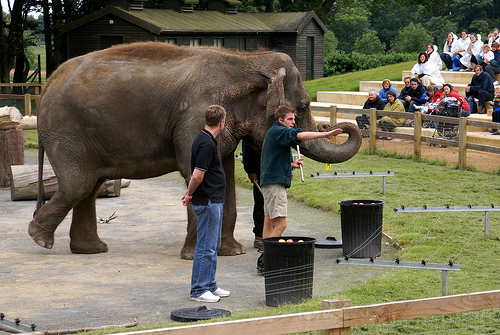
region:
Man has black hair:
[203, 105, 221, 127]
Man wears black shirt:
[194, 138, 217, 165]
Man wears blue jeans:
[191, 208, 218, 286]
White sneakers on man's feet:
[187, 274, 235, 304]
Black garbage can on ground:
[258, 231, 322, 306]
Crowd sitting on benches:
[355, 25, 498, 142]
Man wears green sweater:
[263, 127, 289, 177]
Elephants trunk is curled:
[312, 118, 363, 170]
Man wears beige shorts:
[254, 183, 297, 221]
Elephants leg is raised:
[23, 189, 64, 265]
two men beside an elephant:
[26, 40, 376, 315]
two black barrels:
[248, 180, 398, 317]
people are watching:
[351, 19, 493, 172]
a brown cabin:
[37, 0, 346, 128]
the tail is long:
[22, 96, 58, 233]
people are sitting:
[341, 22, 496, 147]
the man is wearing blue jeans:
[164, 99, 245, 312]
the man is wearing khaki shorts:
[258, 99, 322, 269]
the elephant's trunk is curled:
[253, 43, 374, 172]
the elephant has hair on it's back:
[71, 36, 308, 88]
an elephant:
[57, 41, 300, 155]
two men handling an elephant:
[190, 86, 313, 245]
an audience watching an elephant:
[344, 28, 499, 133]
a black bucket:
[267, 233, 314, 302]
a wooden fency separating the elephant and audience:
[338, 102, 497, 171]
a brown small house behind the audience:
[150, 13, 352, 68]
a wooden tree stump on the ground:
[4, 158, 80, 198]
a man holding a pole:
[270, 105, 320, 202]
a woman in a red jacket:
[435, 78, 465, 113]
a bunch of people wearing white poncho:
[408, 21, 491, 71]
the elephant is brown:
[3, 13, 350, 233]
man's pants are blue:
[166, 181, 234, 294]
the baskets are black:
[240, 177, 414, 294]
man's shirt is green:
[256, 93, 316, 189]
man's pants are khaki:
[248, 179, 303, 224]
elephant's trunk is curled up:
[290, 100, 364, 170]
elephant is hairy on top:
[54, 16, 343, 117]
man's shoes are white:
[166, 273, 246, 315]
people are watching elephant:
[330, 1, 497, 146]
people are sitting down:
[347, 1, 497, 146]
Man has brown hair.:
[269, 97, 309, 159]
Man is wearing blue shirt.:
[265, 119, 292, 164]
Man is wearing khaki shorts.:
[261, 200, 289, 213]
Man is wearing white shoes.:
[189, 280, 243, 305]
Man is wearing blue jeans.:
[185, 202, 230, 264]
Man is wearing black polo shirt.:
[191, 141, 248, 200]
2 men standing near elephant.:
[124, 45, 341, 224]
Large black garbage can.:
[253, 212, 320, 305]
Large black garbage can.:
[348, 202, 398, 277]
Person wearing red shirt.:
[440, 87, 460, 114]